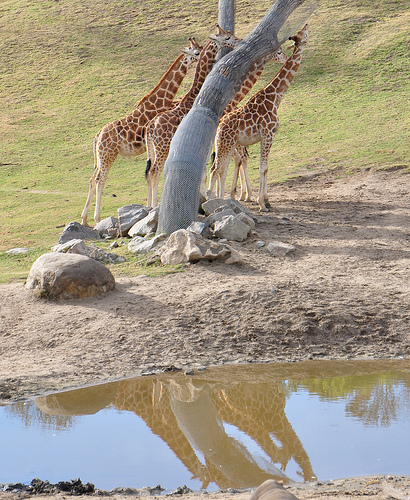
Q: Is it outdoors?
A: Yes, it is outdoors.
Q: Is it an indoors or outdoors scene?
A: It is outdoors.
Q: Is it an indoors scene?
A: No, it is outdoors.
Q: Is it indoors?
A: No, it is outdoors.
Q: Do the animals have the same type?
A: Yes, all the animals are giraffes.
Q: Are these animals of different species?
A: No, all the animals are giraffes.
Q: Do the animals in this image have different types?
A: No, all the animals are giraffes.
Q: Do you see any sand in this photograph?
A: Yes, there is sand.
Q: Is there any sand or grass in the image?
A: Yes, there is sand.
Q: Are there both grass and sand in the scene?
A: Yes, there are both sand and grass.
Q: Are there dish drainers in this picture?
A: No, there are no dish drainers.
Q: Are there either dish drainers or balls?
A: No, there are no dish drainers or balls.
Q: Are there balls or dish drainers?
A: No, there are no dish drainers or balls.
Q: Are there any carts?
A: No, there are no carts.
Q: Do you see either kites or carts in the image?
A: No, there are no carts or kites.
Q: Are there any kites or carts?
A: No, there are no carts or kites.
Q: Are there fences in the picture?
A: No, there are no fences.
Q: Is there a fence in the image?
A: No, there are no fences.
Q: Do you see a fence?
A: No, there are no fences.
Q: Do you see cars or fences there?
A: No, there are no fences or cars.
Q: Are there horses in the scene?
A: No, there are no horses.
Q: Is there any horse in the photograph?
A: No, there are no horses.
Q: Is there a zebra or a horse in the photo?
A: No, there are no horses or zebras.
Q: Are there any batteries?
A: No, there are no batteries.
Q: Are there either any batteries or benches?
A: No, there are no batteries or benches.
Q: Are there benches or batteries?
A: No, there are no batteries or benches.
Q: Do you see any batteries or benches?
A: No, there are no batteries or benches.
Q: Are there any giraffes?
A: Yes, there is a giraffe.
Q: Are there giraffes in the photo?
A: Yes, there is a giraffe.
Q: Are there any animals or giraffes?
A: Yes, there is a giraffe.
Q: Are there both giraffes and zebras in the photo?
A: No, there is a giraffe but no zebras.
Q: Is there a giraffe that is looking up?
A: Yes, there is a giraffe that is looking up.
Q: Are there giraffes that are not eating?
A: Yes, there is a giraffe that is looking up.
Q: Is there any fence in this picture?
A: No, there are no fences.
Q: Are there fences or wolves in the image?
A: No, there are no fences or wolves.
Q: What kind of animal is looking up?
A: The animal is a giraffe.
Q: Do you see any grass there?
A: Yes, there is grass.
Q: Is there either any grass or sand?
A: Yes, there is grass.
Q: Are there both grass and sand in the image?
A: Yes, there are both grass and sand.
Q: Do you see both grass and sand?
A: Yes, there are both grass and sand.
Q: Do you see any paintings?
A: No, there are no paintings.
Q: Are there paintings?
A: No, there are no paintings.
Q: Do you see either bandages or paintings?
A: No, there are no paintings or bandages.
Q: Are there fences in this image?
A: No, there are no fences.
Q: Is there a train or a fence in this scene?
A: No, there are no fences or trains.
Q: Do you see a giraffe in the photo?
A: Yes, there is a giraffe.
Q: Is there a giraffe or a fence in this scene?
A: Yes, there is a giraffe.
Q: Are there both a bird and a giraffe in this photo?
A: No, there is a giraffe but no birds.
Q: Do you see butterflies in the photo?
A: No, there are no butterflies.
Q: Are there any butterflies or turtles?
A: No, there are no butterflies or turtles.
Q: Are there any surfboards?
A: No, there are no surfboards.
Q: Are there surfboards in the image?
A: No, there are no surfboards.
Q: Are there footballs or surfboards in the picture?
A: No, there are no surfboards or footballs.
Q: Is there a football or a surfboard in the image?
A: No, there are no surfboards or footballs.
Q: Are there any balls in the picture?
A: No, there are no balls.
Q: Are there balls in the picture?
A: No, there are no balls.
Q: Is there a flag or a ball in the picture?
A: No, there are no balls or flags.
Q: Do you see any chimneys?
A: No, there are no chimneys.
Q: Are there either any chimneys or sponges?
A: No, there are no chimneys or sponges.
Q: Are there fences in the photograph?
A: No, there are no fences.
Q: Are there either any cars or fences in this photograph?
A: No, there are no fences or cars.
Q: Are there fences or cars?
A: No, there are no fences or cars.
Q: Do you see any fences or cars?
A: No, there are no fences or cars.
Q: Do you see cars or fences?
A: No, there are no fences or cars.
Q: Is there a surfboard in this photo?
A: No, there are no surfboards.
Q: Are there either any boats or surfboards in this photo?
A: No, there are no surfboards or boats.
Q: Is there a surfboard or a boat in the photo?
A: No, there are no surfboards or boats.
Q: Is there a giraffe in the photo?
A: Yes, there is a giraffe.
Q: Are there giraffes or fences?
A: Yes, there is a giraffe.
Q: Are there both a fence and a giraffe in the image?
A: No, there is a giraffe but no fences.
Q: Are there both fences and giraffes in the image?
A: No, there is a giraffe but no fences.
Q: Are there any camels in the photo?
A: No, there are no camels.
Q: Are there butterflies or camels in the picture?
A: No, there are no camels or butterflies.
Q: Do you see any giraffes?
A: Yes, there is a giraffe.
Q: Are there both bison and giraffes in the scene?
A: No, there is a giraffe but no bison.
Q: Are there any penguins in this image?
A: No, there are no penguins.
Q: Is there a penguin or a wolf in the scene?
A: No, there are no penguins or wolves.